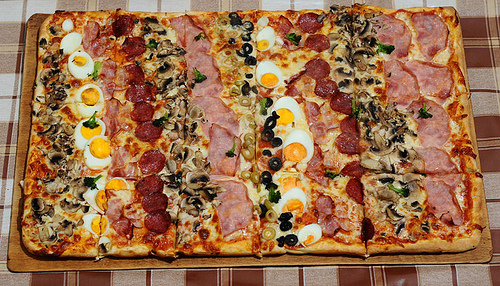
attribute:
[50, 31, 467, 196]
pizza — meat, veggie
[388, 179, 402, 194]
broccoli — green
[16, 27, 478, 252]
pizza — spicy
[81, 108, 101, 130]
broccoli piece — small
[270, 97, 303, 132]
egg — hard boiled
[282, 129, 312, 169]
egg — hard boiled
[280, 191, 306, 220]
egg — hard boiled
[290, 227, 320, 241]
egg — hard boiled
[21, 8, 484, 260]
pizza — big, thin crust, rectangular, brown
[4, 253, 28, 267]
tray — brown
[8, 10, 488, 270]
cutting board — rectangular, wooden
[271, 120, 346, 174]
spice — white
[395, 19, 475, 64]
spice — red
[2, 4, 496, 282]
tablecloth — plaid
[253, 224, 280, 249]
olive — green